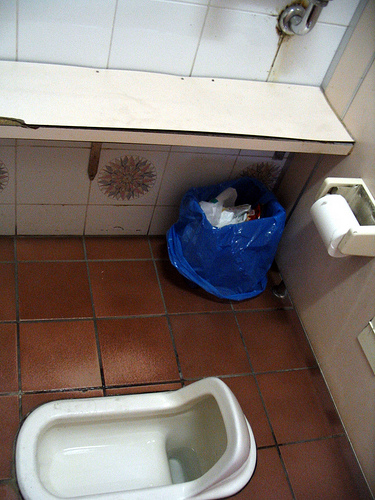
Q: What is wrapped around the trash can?
A: A blue bag.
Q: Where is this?
A: The bathroom.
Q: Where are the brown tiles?
A: On the floor.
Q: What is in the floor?
A: A urinal.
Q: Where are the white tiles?
A: On the wall.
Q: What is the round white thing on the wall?
A: Toilet paper.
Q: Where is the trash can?
A: Under shelf.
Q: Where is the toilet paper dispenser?
A: Right wall.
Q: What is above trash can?
A: Shelf.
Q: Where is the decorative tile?
A: Beside trash can.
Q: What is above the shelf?
A: Metal turn knob.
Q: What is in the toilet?
A: Water.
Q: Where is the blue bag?
A: Trash can.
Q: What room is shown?
A: Bathroom.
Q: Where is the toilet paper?
A: Hanging on the wall.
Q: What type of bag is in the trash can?
A: Plastic.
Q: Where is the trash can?
A: In the corner.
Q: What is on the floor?
A: Tile.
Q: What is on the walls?
A: Tile.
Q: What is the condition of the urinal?
A: Clean.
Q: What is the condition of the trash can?
A: Full.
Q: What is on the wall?
A: White bench.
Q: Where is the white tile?
A: On wall.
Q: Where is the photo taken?
A: Bathroom.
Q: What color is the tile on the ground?
A: Brown.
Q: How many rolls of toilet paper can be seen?
A: One.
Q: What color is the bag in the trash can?
A: Blue.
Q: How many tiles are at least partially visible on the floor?
A: Twenty two.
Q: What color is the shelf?
A: White.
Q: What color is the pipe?
A: Silver.